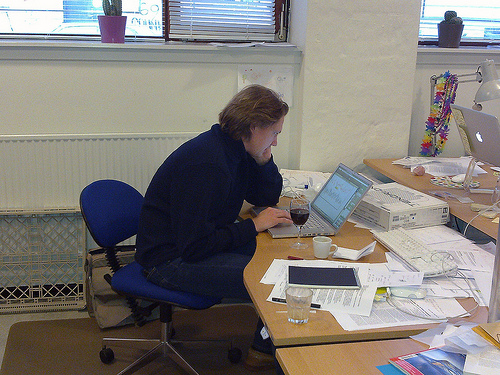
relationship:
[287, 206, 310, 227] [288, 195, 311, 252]
wine in glass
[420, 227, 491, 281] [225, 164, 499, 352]
paper on desk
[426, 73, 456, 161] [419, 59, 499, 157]
necklace on lamp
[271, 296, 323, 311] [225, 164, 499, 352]
pen on desk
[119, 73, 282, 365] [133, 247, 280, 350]
man wearing jeans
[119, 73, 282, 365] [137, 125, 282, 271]
man wearing sweater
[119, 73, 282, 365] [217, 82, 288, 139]
man has hair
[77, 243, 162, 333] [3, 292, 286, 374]
bag on floor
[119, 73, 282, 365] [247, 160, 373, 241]
man working with laptop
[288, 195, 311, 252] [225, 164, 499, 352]
glass on desk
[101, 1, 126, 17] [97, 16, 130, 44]
cactus in pot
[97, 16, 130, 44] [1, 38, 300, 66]
pot on ledge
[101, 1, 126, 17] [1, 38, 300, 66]
cactus on ledge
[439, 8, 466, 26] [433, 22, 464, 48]
cactus in pot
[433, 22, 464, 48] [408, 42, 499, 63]
pot on ledge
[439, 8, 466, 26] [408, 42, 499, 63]
cactus on ledge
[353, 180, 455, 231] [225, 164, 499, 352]
box on desk